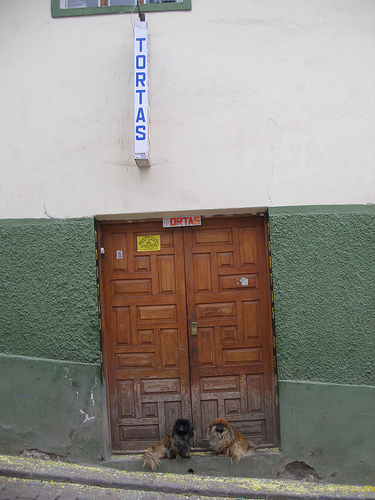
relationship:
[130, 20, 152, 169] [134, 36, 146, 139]
sign with words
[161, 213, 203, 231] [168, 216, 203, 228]
sign with lettering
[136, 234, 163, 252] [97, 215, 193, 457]
sign on door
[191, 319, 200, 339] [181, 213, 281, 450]
handle on door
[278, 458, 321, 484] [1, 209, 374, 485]
hole in wall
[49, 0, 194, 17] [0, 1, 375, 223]
window on building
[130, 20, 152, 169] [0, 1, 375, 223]
sign on building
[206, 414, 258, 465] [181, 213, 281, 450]
dog sitting in front of door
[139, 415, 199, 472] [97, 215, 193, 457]
dog sitting in front of door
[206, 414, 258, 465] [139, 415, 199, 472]
dog sitting next to dog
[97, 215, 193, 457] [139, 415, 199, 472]
door behind dog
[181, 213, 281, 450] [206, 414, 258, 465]
door behind dog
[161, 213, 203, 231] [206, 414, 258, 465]
sign above dog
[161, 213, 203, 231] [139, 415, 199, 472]
sign above dog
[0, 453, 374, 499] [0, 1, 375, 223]
street in front of building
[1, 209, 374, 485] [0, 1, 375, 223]
wall of building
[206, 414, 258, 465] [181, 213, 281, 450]
dog in front of door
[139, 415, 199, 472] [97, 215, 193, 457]
dog in front of door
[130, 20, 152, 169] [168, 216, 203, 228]
sign with lettering